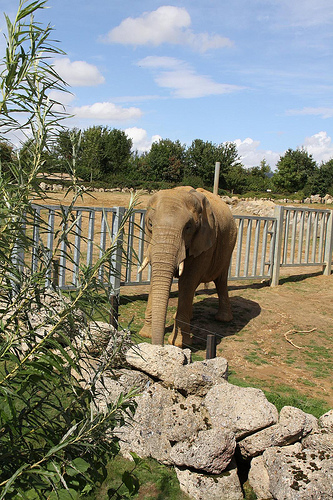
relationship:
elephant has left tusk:
[128, 179, 276, 346] [126, 232, 149, 283]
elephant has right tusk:
[128, 179, 276, 346] [176, 257, 198, 279]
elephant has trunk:
[128, 179, 276, 346] [140, 235, 172, 326]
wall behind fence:
[23, 304, 325, 498] [123, 292, 216, 350]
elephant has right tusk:
[128, 179, 276, 346] [136, 254, 151, 272]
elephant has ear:
[128, 179, 276, 346] [137, 180, 161, 236]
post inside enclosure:
[212, 149, 220, 198] [20, 168, 332, 409]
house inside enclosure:
[28, 162, 96, 187] [20, 168, 332, 409]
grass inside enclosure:
[25, 383, 182, 468] [20, 168, 332, 409]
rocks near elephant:
[71, 337, 329, 485] [128, 179, 276, 346]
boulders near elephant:
[71, 324, 332, 494] [128, 179, 276, 346]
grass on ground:
[25, 383, 182, 468] [219, 285, 329, 402]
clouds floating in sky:
[44, 11, 203, 134] [204, 18, 330, 124]